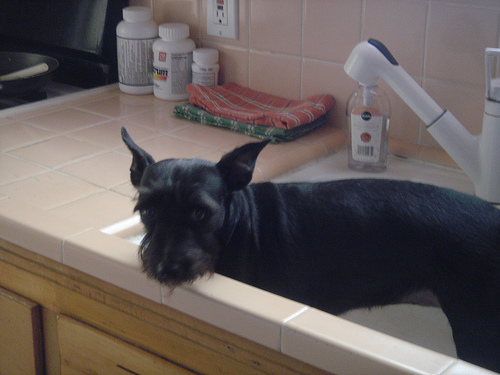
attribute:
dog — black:
[117, 133, 483, 292]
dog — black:
[106, 113, 494, 374]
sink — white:
[108, 28, 500, 374]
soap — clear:
[339, 76, 396, 179]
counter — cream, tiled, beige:
[2, 70, 302, 218]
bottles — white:
[109, 2, 224, 101]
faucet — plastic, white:
[345, 37, 477, 169]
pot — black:
[3, 46, 66, 104]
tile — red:
[7, 90, 189, 186]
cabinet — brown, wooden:
[9, 301, 252, 374]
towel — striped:
[177, 77, 341, 125]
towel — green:
[177, 127, 314, 145]